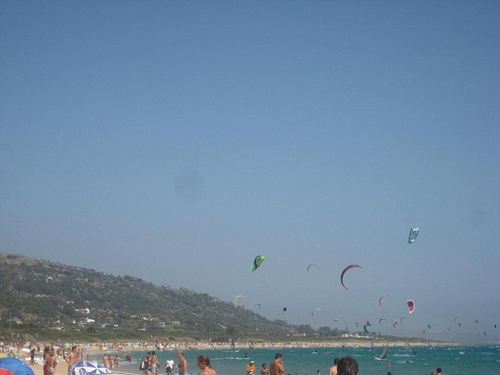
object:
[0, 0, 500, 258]
sky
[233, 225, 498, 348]
parasails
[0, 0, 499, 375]
air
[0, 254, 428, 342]
trees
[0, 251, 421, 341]
hill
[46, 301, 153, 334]
buildings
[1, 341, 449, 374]
crowd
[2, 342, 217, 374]
beach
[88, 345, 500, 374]
ocean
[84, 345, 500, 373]
water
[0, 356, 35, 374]
umbrellas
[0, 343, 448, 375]
people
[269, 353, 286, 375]
man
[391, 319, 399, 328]
parasail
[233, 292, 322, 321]
kites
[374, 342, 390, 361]
sail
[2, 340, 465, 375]
sand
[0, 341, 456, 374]
shore line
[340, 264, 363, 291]
kite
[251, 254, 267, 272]
kite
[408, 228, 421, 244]
kite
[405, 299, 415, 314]
kite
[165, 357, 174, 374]
person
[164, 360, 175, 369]
shirt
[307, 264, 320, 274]
kite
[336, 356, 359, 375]
person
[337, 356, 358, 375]
hair